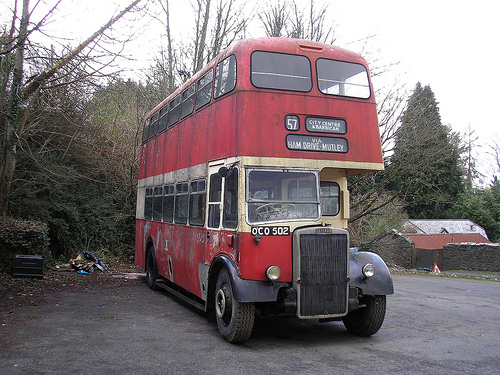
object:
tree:
[383, 82, 466, 219]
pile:
[69, 250, 107, 274]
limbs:
[5, 219, 48, 246]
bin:
[12, 254, 45, 279]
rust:
[154, 228, 204, 251]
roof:
[407, 232, 491, 249]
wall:
[442, 242, 500, 270]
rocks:
[454, 246, 478, 266]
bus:
[134, 37, 395, 346]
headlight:
[265, 265, 281, 280]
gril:
[300, 233, 348, 317]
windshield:
[245, 171, 319, 224]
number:
[287, 118, 297, 129]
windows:
[144, 179, 206, 228]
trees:
[2, 63, 139, 246]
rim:
[214, 282, 233, 325]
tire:
[215, 269, 257, 344]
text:
[287, 118, 345, 152]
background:
[282, 111, 349, 154]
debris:
[69, 250, 108, 275]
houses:
[403, 233, 493, 269]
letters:
[287, 138, 344, 152]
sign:
[283, 113, 349, 153]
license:
[251, 226, 290, 236]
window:
[245, 168, 321, 225]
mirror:
[219, 167, 230, 178]